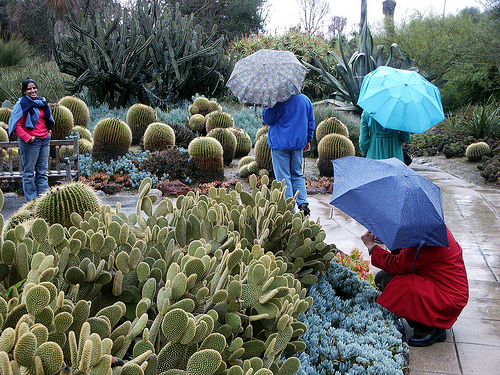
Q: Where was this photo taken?
A: A cactus garden.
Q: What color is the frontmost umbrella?
A: Blue.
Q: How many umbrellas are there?
A: Three.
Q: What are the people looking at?
A: Cacti.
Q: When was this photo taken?
A: Daytime.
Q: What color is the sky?
A: White.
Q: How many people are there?
A: Four.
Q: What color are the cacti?
A: Green.